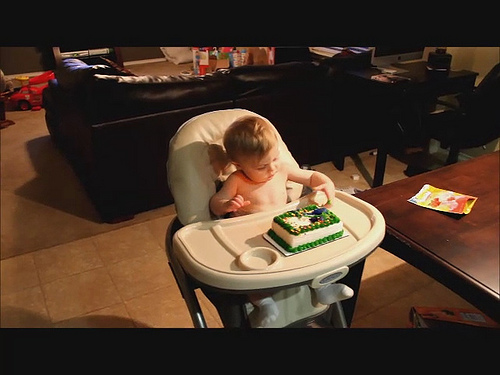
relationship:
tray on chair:
[169, 180, 389, 297] [167, 106, 351, 329]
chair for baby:
[167, 106, 351, 329] [207, 112, 354, 324]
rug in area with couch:
[10, 97, 83, 248] [39, 51, 401, 224]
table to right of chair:
[348, 145, 500, 305] [167, 106, 351, 329]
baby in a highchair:
[207, 112, 354, 324] [161, 92, 401, 329]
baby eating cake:
[207, 112, 354, 324] [263, 203, 345, 255]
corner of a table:
[351, 172, 418, 245] [339, 145, 496, 335]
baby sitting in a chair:
[207, 112, 354, 324] [167, 106, 351, 329]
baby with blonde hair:
[207, 112, 354, 324] [224, 116, 277, 157]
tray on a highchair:
[169, 180, 389, 297] [119, 99, 405, 339]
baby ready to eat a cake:
[207, 112, 354, 324] [263, 203, 345, 255]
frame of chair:
[160, 218, 351, 327] [161, 204, 384, 320]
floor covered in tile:
[0, 105, 497, 327] [0, 110, 496, 330]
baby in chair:
[207, 112, 354, 324] [167, 106, 351, 329]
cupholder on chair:
[244, 247, 274, 272] [167, 106, 351, 329]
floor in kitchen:
[61, 258, 135, 308] [6, 50, 473, 324]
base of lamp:
[423, 44, 454, 74] [426, 48, 456, 73]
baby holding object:
[207, 112, 354, 324] [311, 191, 328, 202]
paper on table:
[418, 180, 478, 228] [341, 163, 499, 310]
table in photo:
[348, 145, 498, 297] [14, 43, 498, 333]